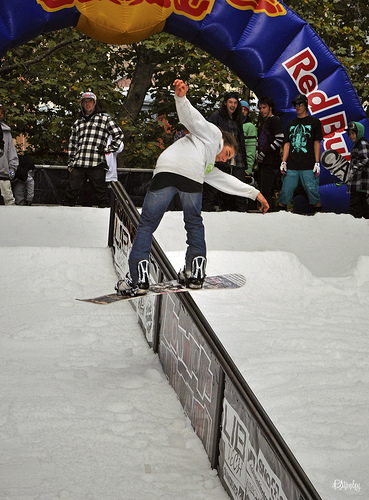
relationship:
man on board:
[115, 78, 270, 288] [74, 273, 245, 305]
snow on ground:
[248, 233, 283, 251] [1, 206, 367, 498]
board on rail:
[74, 273, 245, 305] [109, 182, 320, 499]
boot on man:
[116, 259, 150, 295] [115, 78, 270, 288]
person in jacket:
[69, 91, 123, 209] [67, 112, 123, 171]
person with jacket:
[69, 91, 123, 209] [67, 112, 123, 171]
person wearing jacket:
[69, 91, 123, 209] [67, 112, 123, 171]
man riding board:
[115, 78, 270, 288] [74, 273, 245, 305]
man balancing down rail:
[115, 78, 270, 288] [109, 182, 320, 499]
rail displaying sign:
[109, 182, 320, 499] [159, 276, 220, 442]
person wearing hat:
[241, 100, 257, 178] [238, 100, 250, 108]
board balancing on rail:
[74, 273, 245, 305] [109, 182, 320, 499]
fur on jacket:
[80, 109, 103, 121] [67, 112, 123, 171]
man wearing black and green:
[280, 94, 324, 217] [283, 117, 323, 172]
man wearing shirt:
[115, 78, 270, 288] [153, 95, 261, 201]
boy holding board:
[342, 121, 368, 224] [318, 146, 351, 187]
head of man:
[215, 130, 238, 165] [115, 78, 270, 288]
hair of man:
[222, 130, 238, 147] [115, 78, 270, 288]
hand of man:
[174, 78, 189, 98] [115, 78, 270, 288]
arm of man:
[173, 93, 220, 138] [115, 78, 270, 288]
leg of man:
[128, 190, 176, 284] [115, 78, 270, 288]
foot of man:
[173, 266, 205, 293] [115, 78, 270, 288]